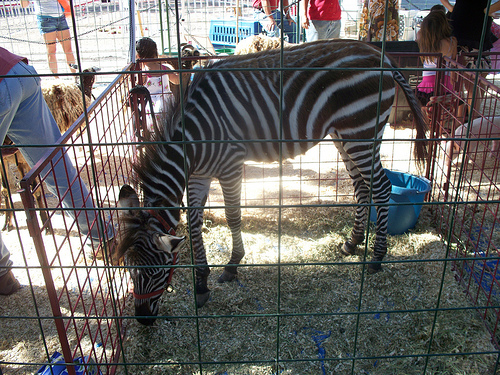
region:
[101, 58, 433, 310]
a zebra eating grains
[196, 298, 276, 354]
grains on the bottom of a zebra cage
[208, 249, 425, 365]
green metal wiring on a cage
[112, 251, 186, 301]
a red harness on a zebra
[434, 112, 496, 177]
a pink pig in a cage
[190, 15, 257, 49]
a green plastic pet carrier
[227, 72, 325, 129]
the black and white stripes on the side of a zebra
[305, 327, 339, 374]
the blue tarp on the bottom of the cage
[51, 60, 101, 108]
the side of a black goat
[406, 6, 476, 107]
the back of a girl with long hair and pink skirt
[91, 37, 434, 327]
zebra in a petting zoo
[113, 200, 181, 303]
red harness on a zebra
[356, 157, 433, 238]
blue bucket in a zebra's cage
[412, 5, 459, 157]
girl in bright pink skirt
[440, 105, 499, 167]
pink pig at a petting zoo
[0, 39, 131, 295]
person in a red shirt leaning over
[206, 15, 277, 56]
blue kennel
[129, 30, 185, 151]
girl in a white dress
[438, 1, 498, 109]
woman with a black top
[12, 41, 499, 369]
zebra's metal cage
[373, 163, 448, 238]
a big blue bucket.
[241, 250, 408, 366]
grass is in the cage.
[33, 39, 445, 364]
a huge metal cage.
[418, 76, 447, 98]
a woman is wearing a pink skirt.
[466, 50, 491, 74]
a woman is wearing white and black shorts.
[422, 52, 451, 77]
a woman is wearing a white shirt.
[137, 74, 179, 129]
a little girl is wearing a flowered dress.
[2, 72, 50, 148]
a man is wearing blue jeans.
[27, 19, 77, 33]
a woman is wearing blue jean shorts.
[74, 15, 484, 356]
a zebra is eating the grass.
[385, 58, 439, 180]
tail of a zebra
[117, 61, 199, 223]
mane of a zebra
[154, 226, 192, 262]
ear of a zebra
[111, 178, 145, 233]
ear of a zebra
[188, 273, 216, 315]
hoof of a zebra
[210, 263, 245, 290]
hoof of a zebra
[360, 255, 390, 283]
hoof of a zebra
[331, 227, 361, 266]
hoof of a zebra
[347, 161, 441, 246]
blue bucket near a zebra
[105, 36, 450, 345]
zebra wearing a red halter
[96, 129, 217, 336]
zebra is eating hay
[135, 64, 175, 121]
girl's shirt is white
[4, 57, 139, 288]
man wearing blue jeans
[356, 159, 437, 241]
the container is blue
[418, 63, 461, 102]
girl's skirt is pink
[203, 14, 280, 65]
the crate is blue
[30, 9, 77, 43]
the shorts are blue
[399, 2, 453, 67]
girl's hair is brown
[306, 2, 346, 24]
man's shirt is red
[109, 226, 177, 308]
red strap on zebra